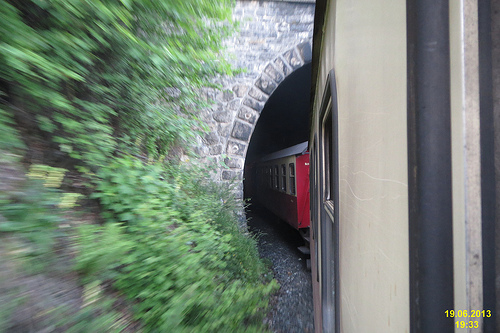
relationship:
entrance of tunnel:
[236, 57, 314, 297] [224, 34, 317, 330]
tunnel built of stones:
[224, 34, 317, 330] [177, 12, 309, 268]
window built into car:
[321, 99, 334, 215] [308, 0, 479, 330]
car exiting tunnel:
[308, 0, 479, 330] [121, 2, 312, 273]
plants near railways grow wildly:
[0, 74, 284, 333] [106, 167, 171, 200]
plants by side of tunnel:
[0, 0, 284, 333] [243, 60, 313, 290]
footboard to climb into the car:
[296, 229, 309, 263] [271, 137, 309, 229]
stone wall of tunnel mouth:
[179, 20, 275, 210] [192, 0, 354, 330]